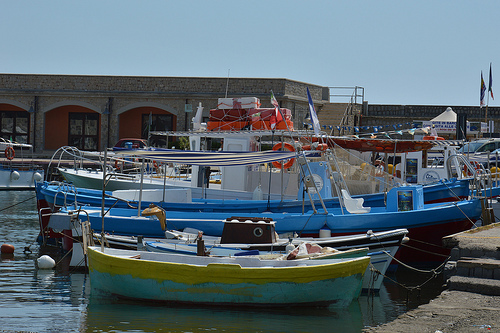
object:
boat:
[143, 170, 222, 184]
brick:
[252, 80, 263, 87]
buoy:
[0, 244, 14, 254]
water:
[0, 190, 446, 333]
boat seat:
[341, 189, 371, 214]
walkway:
[360, 222, 500, 333]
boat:
[85, 245, 371, 308]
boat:
[0, 136, 46, 191]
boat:
[348, 124, 464, 186]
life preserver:
[272, 142, 295, 169]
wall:
[0, 74, 329, 161]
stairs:
[303, 103, 361, 136]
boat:
[58, 97, 298, 200]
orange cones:
[142, 203, 166, 216]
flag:
[306, 86, 323, 142]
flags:
[478, 62, 494, 139]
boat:
[39, 106, 489, 264]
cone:
[430, 107, 469, 122]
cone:
[271, 89, 282, 112]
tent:
[430, 107, 471, 134]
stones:
[441, 292, 483, 330]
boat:
[93, 216, 410, 293]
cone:
[142, 203, 164, 216]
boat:
[40, 86, 474, 254]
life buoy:
[4, 146, 14, 160]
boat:
[144, 241, 390, 288]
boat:
[33, 169, 74, 244]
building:
[360, 104, 499, 140]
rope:
[367, 229, 452, 320]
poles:
[479, 70, 483, 138]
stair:
[442, 235, 500, 297]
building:
[0, 74, 365, 159]